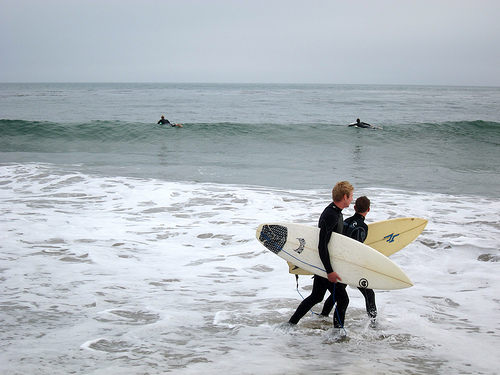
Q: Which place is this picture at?
A: It is at the ocean.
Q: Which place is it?
A: It is an ocean.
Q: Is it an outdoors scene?
A: Yes, it is outdoors.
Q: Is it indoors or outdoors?
A: It is outdoors.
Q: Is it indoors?
A: No, it is outdoors.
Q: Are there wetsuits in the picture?
A: Yes, there is a wetsuit.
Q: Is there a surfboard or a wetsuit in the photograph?
A: Yes, there is a wetsuit.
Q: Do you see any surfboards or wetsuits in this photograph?
A: Yes, there is a wetsuit.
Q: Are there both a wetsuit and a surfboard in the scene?
A: Yes, there are both a wetsuit and a surfboard.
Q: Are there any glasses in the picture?
A: No, there are no glasses.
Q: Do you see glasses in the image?
A: No, there are no glasses.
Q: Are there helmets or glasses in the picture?
A: No, there are no glasses or helmets.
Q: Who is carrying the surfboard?
A: The man is carrying the surfboard.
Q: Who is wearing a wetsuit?
A: The man is wearing a wetsuit.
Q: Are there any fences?
A: No, there are no fences.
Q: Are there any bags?
A: No, there are no bags.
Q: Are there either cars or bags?
A: No, there are no bags or cars.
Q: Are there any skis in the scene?
A: No, there are no skis.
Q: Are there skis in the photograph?
A: No, there are no skis.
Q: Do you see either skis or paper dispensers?
A: No, there are no skis or paper dispensers.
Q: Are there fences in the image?
A: No, there are no fences.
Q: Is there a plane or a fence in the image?
A: No, there are no fences or airplanes.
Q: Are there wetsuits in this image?
A: Yes, there is a wetsuit.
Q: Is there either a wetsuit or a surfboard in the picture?
A: Yes, there is a wetsuit.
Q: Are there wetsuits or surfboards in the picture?
A: Yes, there is a wetsuit.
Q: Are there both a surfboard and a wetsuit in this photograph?
A: Yes, there are both a wetsuit and a surfboard.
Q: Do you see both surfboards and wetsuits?
A: Yes, there are both a wetsuit and a surfboard.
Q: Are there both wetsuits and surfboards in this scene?
A: Yes, there are both a wetsuit and a surfboard.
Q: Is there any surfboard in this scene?
A: Yes, there is a surfboard.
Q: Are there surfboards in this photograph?
A: Yes, there is a surfboard.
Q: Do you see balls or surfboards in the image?
A: Yes, there is a surfboard.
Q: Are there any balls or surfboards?
A: Yes, there is a surfboard.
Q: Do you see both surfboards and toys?
A: No, there is a surfboard but no toys.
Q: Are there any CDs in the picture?
A: No, there are no cds.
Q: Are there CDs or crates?
A: No, there are no CDs or crates.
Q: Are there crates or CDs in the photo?
A: No, there are no CDs or crates.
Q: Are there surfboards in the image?
A: Yes, there is a surfboard.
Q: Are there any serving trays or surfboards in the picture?
A: Yes, there is a surfboard.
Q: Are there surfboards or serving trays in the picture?
A: Yes, there is a surfboard.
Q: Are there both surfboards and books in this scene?
A: No, there is a surfboard but no books.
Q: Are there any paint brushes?
A: No, there are no paint brushes.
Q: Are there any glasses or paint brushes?
A: No, there are no paint brushes or glasses.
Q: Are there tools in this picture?
A: No, there are no tools.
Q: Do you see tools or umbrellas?
A: No, there are no tools or umbrellas.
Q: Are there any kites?
A: No, there are no kites.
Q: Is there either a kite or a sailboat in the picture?
A: No, there are no kites or sailboats.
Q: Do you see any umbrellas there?
A: No, there are no umbrellas.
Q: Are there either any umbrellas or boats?
A: No, there are no umbrellas or boats.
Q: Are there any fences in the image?
A: No, there are no fences.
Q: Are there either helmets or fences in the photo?
A: No, there are no fences or helmets.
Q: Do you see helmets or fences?
A: No, there are no fences or helmets.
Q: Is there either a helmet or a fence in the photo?
A: No, there are no fences or helmets.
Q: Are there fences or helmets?
A: No, there are no fences or helmets.